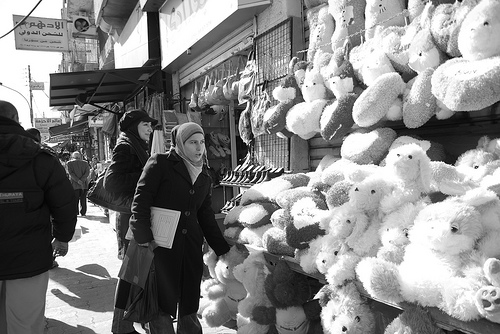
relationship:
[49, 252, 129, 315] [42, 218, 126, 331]
shadow on ground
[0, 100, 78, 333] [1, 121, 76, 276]
man wearing coat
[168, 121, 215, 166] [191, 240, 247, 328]
scarf touching stuffed animal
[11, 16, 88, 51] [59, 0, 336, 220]
sign attached to building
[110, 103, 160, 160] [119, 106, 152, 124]
woman wearing hat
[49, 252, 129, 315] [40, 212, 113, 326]
shadow on sidewalk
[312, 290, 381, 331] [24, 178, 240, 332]
teddy bear on ground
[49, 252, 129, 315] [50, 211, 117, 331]
shadow on ground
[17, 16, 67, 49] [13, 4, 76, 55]
writing on sign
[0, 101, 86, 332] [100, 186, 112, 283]
man has hands behind back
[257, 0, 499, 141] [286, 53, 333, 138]
row of stuffed animal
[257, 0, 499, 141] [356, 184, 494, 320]
row of stuffed animal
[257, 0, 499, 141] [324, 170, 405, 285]
row of stuffed animal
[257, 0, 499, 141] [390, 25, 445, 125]
row of stuffed animal